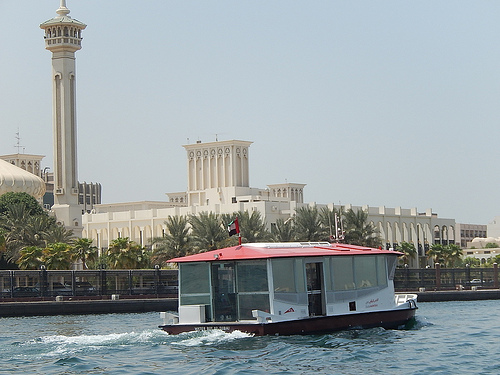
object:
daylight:
[2, 2, 500, 148]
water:
[4, 305, 498, 375]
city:
[5, 0, 497, 310]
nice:
[1, 0, 499, 243]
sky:
[272, 5, 479, 160]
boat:
[156, 245, 419, 338]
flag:
[228, 215, 242, 249]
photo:
[0, 0, 500, 361]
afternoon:
[6, 0, 496, 142]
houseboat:
[161, 232, 422, 341]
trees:
[42, 237, 75, 270]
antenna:
[13, 126, 25, 152]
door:
[305, 260, 325, 316]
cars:
[5, 280, 71, 299]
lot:
[2, 266, 172, 307]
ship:
[163, 237, 417, 337]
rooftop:
[165, 237, 405, 261]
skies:
[102, 5, 493, 118]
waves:
[23, 329, 259, 355]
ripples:
[438, 310, 485, 337]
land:
[6, 276, 173, 308]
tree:
[20, 243, 44, 287]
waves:
[53, 352, 82, 373]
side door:
[305, 261, 325, 317]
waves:
[444, 340, 471, 357]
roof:
[165, 240, 401, 261]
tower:
[38, 2, 90, 294]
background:
[0, 22, 496, 247]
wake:
[39, 330, 212, 358]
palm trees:
[192, 207, 228, 248]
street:
[2, 247, 496, 301]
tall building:
[36, 0, 87, 246]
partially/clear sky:
[146, 20, 467, 119]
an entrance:
[210, 259, 238, 321]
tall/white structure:
[180, 132, 256, 214]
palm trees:
[156, 210, 189, 252]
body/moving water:
[60, 331, 447, 371]